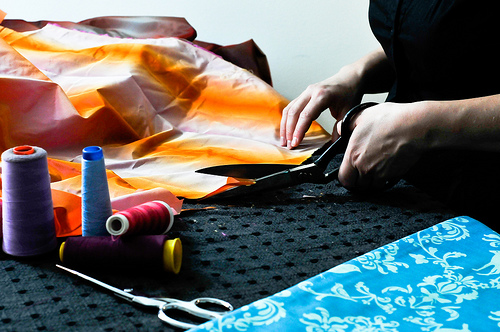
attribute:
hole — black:
[235, 262, 247, 276]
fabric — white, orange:
[10, 21, 285, 209]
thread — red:
[110, 199, 171, 235]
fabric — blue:
[183, 213, 484, 330]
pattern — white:
[183, 213, 484, 329]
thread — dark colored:
[60, 231, 170, 275]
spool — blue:
[81, 144, 112, 238]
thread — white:
[80, 155, 113, 236]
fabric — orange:
[1, 10, 335, 238]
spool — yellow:
[57, 230, 183, 276]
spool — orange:
[10, 143, 36, 154]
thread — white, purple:
[0, 143, 59, 258]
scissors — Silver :
[53, 260, 233, 330]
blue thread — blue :
[66, 140, 143, 268]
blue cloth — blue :
[179, 210, 498, 328]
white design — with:
[344, 256, 468, 318]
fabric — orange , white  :
[27, 24, 345, 212]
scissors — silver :
[64, 249, 244, 329]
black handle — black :
[321, 92, 419, 203]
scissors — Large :
[191, 92, 432, 223]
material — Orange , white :
[80, 36, 278, 221]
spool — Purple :
[55, 232, 189, 285]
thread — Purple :
[63, 232, 193, 275]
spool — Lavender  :
[5, 136, 60, 262]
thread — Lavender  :
[4, 142, 58, 267]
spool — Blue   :
[76, 148, 135, 248]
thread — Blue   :
[71, 137, 130, 259]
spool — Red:
[103, 199, 193, 248]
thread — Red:
[92, 194, 182, 250]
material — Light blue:
[157, 182, 497, 329]